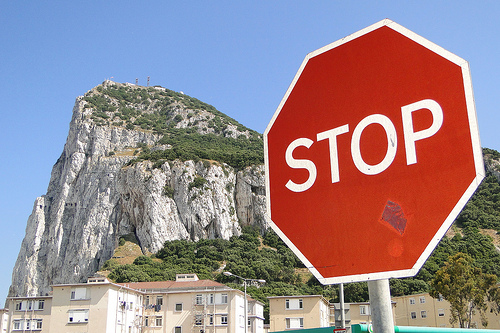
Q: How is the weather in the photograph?
A: It is clear.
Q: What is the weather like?
A: It is clear.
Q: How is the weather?
A: It is clear.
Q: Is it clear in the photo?
A: Yes, it is clear.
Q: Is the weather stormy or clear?
A: It is clear.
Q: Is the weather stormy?
A: No, it is clear.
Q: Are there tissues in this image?
A: No, there are no tissues.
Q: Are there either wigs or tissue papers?
A: No, there are no tissue papers or wigs.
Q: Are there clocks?
A: No, there are no clocks.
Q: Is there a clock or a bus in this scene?
A: No, there are no clocks or buses.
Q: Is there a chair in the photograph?
A: No, there are no chairs.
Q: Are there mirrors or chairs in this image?
A: No, there are no chairs or mirrors.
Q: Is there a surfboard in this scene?
A: No, there are no surfboards.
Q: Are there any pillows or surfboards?
A: No, there are no surfboards or pillows.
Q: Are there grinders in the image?
A: No, there are no grinders.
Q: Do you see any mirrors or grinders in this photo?
A: No, there are no grinders or mirrors.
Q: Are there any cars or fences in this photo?
A: No, there are no cars or fences.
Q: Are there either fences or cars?
A: No, there are no cars or fences.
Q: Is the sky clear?
A: Yes, the sky is clear.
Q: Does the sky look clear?
A: Yes, the sky is clear.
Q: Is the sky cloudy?
A: No, the sky is clear.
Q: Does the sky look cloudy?
A: No, the sky is clear.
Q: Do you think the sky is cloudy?
A: No, the sky is clear.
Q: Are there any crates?
A: No, there are no crates.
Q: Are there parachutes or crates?
A: No, there are no crates or parachutes.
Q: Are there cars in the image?
A: No, there are no cars.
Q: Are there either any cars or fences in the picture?
A: No, there are no cars or fences.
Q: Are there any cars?
A: No, there are no cars.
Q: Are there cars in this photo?
A: No, there are no cars.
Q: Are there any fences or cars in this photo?
A: No, there are no cars or fences.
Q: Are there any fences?
A: No, there are no fences.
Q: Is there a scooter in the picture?
A: No, there are no scooters.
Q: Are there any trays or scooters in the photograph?
A: No, there are no scooters or trays.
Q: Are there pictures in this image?
A: No, there are no pictures.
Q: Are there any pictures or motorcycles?
A: No, there are no pictures or motorcycles.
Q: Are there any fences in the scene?
A: No, there are no fences.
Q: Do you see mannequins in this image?
A: No, there are no mannequins.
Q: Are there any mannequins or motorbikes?
A: No, there are no mannequins or motorbikes.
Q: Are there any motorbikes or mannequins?
A: No, there are no mannequins or motorbikes.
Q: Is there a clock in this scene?
A: No, there are no clocks.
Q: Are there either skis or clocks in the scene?
A: No, there are no clocks or skis.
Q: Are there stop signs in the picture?
A: Yes, there is a stop sign.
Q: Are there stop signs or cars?
A: Yes, there is a stop sign.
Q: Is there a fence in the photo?
A: No, there are no fences.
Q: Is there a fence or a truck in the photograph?
A: No, there are no fences or trucks.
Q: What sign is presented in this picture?
A: The sign is a stop sign.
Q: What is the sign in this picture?
A: The sign is a stop sign.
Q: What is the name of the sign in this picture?
A: The sign is a stop sign.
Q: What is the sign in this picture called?
A: The sign is a stop sign.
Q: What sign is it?
A: The sign is a stop sign.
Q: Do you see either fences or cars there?
A: No, there are no cars or fences.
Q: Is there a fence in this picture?
A: No, there are no fences.